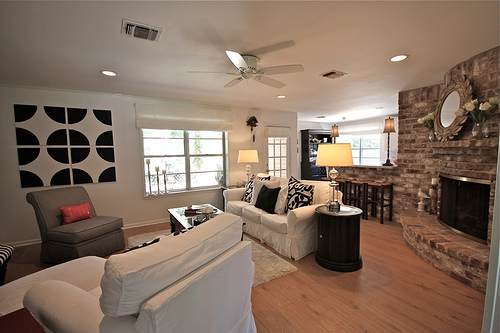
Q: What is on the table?
A: A lamp.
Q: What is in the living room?
A: A white couch.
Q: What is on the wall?
A: A black and white picture.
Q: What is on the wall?
A: A white window.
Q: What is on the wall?
A: A picture.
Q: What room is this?
A: Living room.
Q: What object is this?
A: Couch.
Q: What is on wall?
A: Art.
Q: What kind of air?
A: Black and white.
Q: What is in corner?
A: Fireplace.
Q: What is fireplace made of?
A: Brick.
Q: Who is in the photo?
A: Nobody.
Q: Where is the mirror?
A: Wall.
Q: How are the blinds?
A: Open.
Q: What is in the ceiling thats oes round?
A: Ceiling fan.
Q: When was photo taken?
A: Daytime.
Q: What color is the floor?
A: Oak.